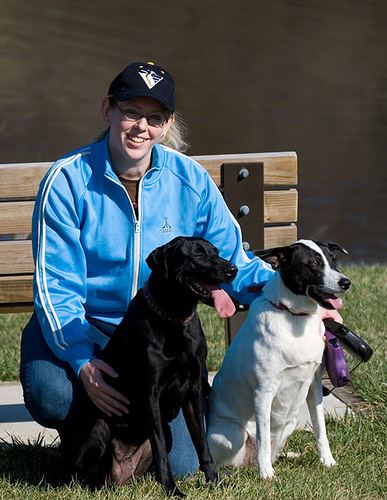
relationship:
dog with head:
[217, 232, 350, 474] [269, 239, 345, 312]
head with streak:
[269, 239, 345, 312] [301, 239, 334, 280]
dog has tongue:
[68, 237, 234, 489] [204, 282, 235, 322]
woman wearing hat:
[22, 62, 263, 481] [108, 65, 179, 110]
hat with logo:
[108, 65, 179, 110] [137, 67, 166, 93]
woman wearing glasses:
[22, 62, 263, 481] [118, 106, 164, 129]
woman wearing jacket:
[22, 62, 263, 481] [22, 143, 277, 367]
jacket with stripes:
[22, 143, 277, 367] [22, 158, 88, 349]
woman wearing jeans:
[22, 62, 263, 481] [30, 316, 207, 478]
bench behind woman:
[5, 152, 306, 297] [22, 62, 263, 481]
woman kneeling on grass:
[22, 62, 263, 481] [2, 267, 387, 498]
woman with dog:
[22, 62, 263, 481] [205, 238, 351, 481]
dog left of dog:
[68, 237, 234, 489] [217, 232, 350, 474]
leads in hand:
[324, 324, 364, 380] [319, 302, 344, 331]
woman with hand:
[22, 62, 263, 481] [319, 302, 344, 331]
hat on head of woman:
[108, 65, 179, 110] [22, 62, 263, 481]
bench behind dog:
[5, 152, 306, 297] [205, 238, 351, 481]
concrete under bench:
[4, 376, 359, 445] [5, 152, 306, 297]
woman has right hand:
[22, 62, 263, 481] [77, 360, 130, 419]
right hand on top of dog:
[77, 360, 130, 419] [68, 237, 234, 489]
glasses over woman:
[118, 106, 164, 129] [22, 62, 263, 481]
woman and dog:
[22, 62, 263, 481] [205, 238, 351, 481]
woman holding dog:
[22, 62, 263, 481] [205, 238, 351, 481]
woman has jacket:
[22, 62, 263, 481] [22, 143, 277, 367]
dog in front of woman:
[217, 232, 350, 474] [22, 62, 263, 481]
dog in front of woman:
[68, 237, 234, 489] [22, 62, 263, 481]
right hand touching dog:
[77, 360, 130, 419] [68, 237, 234, 489]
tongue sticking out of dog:
[204, 282, 235, 322] [68, 237, 234, 489]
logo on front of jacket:
[161, 215, 180, 238] [22, 143, 277, 367]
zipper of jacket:
[119, 180, 143, 297] [22, 143, 277, 367]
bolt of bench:
[237, 169, 251, 179] [5, 152, 306, 297]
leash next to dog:
[323, 336, 348, 386] [217, 232, 350, 474]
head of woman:
[102, 60, 175, 159] [22, 62, 263, 481]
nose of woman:
[135, 111, 153, 134] [22, 62, 263, 481]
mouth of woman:
[125, 134, 151, 146] [22, 62, 263, 481]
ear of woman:
[98, 96, 114, 121] [22, 62, 263, 481]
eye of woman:
[124, 106, 138, 115] [22, 62, 263, 481]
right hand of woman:
[77, 360, 130, 419] [22, 62, 263, 481]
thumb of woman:
[95, 360, 121, 381] [22, 62, 263, 481]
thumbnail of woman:
[112, 369, 118, 377] [22, 62, 263, 481]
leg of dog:
[142, 392, 189, 498] [68, 237, 234, 489]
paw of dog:
[165, 485, 187, 497] [68, 237, 234, 489]